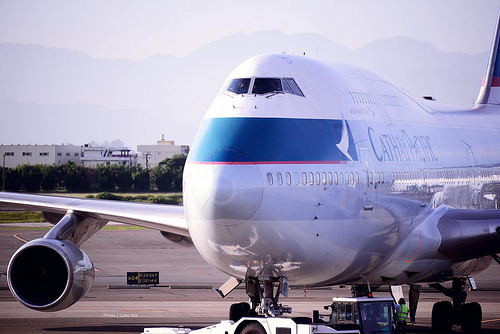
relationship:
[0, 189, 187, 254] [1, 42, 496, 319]
wing on aircraft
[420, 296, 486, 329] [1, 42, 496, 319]
wheels of aircraft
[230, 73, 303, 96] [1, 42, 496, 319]
windows on aircraft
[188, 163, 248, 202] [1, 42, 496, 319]
nose of aircraft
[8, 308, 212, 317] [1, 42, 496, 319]
tarmac on airport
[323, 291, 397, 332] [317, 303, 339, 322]
vehicle loading luggage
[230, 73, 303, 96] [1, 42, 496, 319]
cockpit of aircraft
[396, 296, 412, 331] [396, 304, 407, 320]
he wearing safetyvest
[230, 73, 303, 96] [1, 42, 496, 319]
windshield of plane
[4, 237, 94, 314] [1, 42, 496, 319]
engine of plane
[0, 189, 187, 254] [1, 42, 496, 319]
wing of plane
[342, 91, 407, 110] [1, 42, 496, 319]
windows on plane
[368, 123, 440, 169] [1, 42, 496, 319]
writing on plane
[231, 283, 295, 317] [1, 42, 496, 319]
gear of plane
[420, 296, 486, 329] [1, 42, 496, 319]
wheels of plane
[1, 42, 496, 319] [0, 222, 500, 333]
airplane on road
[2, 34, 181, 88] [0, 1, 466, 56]
mountains in background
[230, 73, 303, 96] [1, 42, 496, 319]
windshield on plane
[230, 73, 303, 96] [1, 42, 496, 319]
windows on airplane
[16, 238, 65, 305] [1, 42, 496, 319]
propellers on airplane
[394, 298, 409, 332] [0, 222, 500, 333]
man on road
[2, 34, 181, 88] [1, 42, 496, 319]
mountains behind plane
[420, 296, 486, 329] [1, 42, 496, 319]
landinggear on aircraft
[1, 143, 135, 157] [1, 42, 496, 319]
buildings behind plane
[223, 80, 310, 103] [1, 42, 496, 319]
cockpit on aircraft